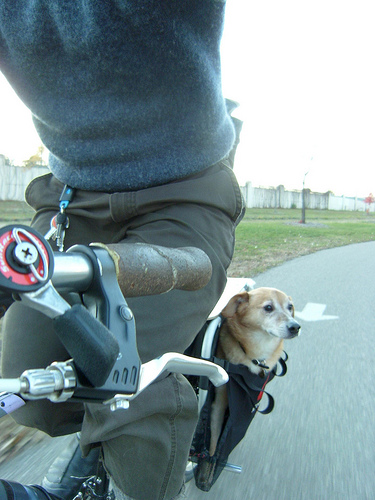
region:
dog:
[225, 284, 308, 409]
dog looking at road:
[224, 288, 320, 420]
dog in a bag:
[222, 295, 285, 488]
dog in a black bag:
[226, 292, 310, 497]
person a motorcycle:
[12, 24, 271, 447]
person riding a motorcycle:
[2, 67, 159, 475]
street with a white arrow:
[272, 262, 366, 457]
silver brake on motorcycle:
[117, 355, 280, 404]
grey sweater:
[12, 22, 243, 187]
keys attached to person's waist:
[42, 179, 93, 274]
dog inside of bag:
[160, 286, 312, 492]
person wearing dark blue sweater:
[7, 4, 239, 186]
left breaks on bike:
[37, 344, 234, 406]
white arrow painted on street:
[286, 301, 336, 326]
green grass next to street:
[0, 200, 373, 277]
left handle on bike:
[65, 240, 211, 289]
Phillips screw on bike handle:
[14, 243, 37, 264]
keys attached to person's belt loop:
[39, 184, 72, 253]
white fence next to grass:
[236, 187, 372, 213]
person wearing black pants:
[26, 168, 239, 498]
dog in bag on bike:
[212, 283, 314, 478]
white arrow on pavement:
[293, 295, 337, 329]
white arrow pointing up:
[291, 298, 337, 328]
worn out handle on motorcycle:
[109, 242, 220, 302]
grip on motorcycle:
[55, 343, 226, 414]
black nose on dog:
[264, 315, 313, 352]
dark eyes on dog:
[251, 296, 297, 315]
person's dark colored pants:
[33, 137, 252, 236]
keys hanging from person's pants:
[36, 176, 72, 246]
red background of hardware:
[0, 228, 52, 289]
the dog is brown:
[225, 283, 312, 353]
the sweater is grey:
[38, 8, 222, 164]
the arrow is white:
[289, 294, 342, 337]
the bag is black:
[230, 371, 293, 467]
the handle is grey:
[104, 231, 225, 292]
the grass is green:
[268, 219, 347, 246]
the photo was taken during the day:
[0, 183, 371, 473]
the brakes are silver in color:
[146, 350, 233, 393]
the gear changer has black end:
[36, 297, 124, 386]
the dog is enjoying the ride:
[234, 292, 312, 356]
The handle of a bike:
[79, 237, 215, 297]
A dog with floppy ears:
[188, 282, 303, 488]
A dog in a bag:
[172, 287, 301, 490]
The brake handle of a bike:
[13, 344, 230, 407]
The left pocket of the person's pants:
[203, 161, 250, 228]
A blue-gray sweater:
[1, 75, 239, 188]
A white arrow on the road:
[293, 296, 339, 331]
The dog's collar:
[228, 331, 284, 372]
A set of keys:
[42, 181, 80, 249]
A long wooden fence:
[237, 182, 374, 211]